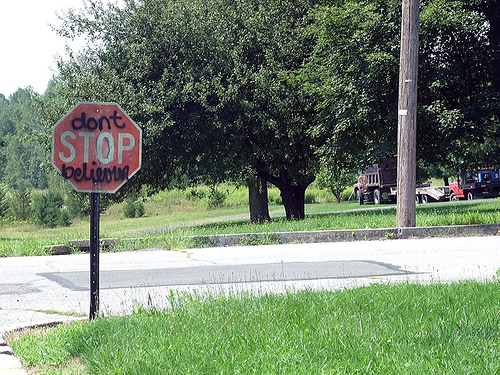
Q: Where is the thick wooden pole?
A: On right.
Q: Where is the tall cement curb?
A: Near street.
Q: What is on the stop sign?
A: Graffiti.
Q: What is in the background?
A: 2 trees.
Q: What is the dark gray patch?
A: Road.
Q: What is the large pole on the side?
A: Telephone pole.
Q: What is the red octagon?
A: Stop sign.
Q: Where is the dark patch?
A: Middle road.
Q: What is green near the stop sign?
A: Grass.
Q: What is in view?
A: Thick green grass area.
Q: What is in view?
A: High green grass area.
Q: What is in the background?
A: Set of green trees.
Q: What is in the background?
A: Healthy green trees.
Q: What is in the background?
A: Big set of green trees.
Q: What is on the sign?
A: Black graffiti.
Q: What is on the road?
A: A patch.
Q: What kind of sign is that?
A: Red metal stop sign.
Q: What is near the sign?
A: An overgrown plot of grass.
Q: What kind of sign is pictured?
A: A stop sign.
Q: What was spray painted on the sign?
A: Graffiti.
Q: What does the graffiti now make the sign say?
A: Don't stop believing.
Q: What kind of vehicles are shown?
A: Trucks.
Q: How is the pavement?
A: Patched.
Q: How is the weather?
A: Sunny.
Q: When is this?
A: Daytime.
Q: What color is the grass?
A: Green.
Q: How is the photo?
A: Clear.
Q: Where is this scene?
A: On the street.